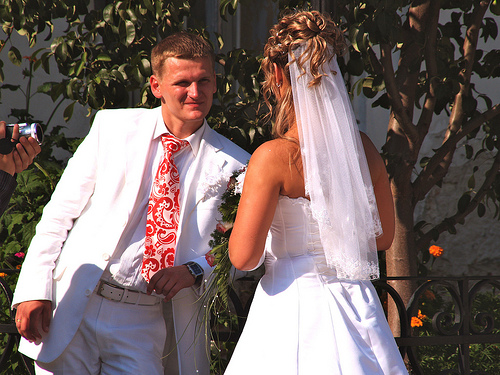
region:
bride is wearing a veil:
[277, 34, 401, 299]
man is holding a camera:
[6, 114, 61, 184]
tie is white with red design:
[130, 118, 185, 305]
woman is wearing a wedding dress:
[259, 153, 381, 350]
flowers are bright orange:
[405, 231, 479, 370]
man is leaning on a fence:
[173, 105, 308, 288]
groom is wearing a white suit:
[59, 111, 230, 361]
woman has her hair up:
[270, 15, 352, 77]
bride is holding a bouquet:
[185, 162, 275, 275]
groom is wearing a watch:
[170, 241, 224, 309]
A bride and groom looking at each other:
[70, 67, 370, 303]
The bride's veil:
[285, 57, 395, 274]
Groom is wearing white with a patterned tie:
[142, 77, 220, 353]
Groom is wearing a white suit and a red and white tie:
[37, 70, 228, 348]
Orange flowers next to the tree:
[411, 205, 446, 356]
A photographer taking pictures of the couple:
[0, 102, 38, 223]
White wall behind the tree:
[372, 0, 490, 215]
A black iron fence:
[302, 275, 492, 353]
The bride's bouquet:
[201, 170, 256, 311]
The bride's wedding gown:
[217, 169, 414, 372]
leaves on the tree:
[82, 31, 109, 60]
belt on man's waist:
[97, 285, 154, 304]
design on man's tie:
[156, 170, 174, 241]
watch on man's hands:
[180, 256, 205, 283]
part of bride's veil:
[300, 99, 352, 177]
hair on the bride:
[306, 41, 335, 92]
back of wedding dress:
[271, 283, 358, 351]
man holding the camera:
[0, 117, 42, 179]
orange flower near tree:
[420, 237, 450, 264]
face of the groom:
[158, 61, 222, 121]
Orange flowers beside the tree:
[385, 223, 461, 343]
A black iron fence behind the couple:
[215, 271, 491, 366]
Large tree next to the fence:
[361, 30, 441, 335]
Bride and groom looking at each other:
[45, 60, 411, 366]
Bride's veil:
[240, 55, 395, 290]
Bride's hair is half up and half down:
[260, 35, 345, 155]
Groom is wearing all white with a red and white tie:
[70, 65, 225, 371]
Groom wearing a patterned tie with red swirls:
[151, 115, 181, 295]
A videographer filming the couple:
[2, 101, 64, 199]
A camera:
[2, 111, 54, 188]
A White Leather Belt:
[97, 275, 169, 322]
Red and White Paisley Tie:
[135, 127, 185, 302]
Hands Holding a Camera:
[0, 110, 45, 190]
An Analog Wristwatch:
[185, 257, 216, 304]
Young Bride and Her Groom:
[110, 5, 415, 271]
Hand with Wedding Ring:
[6, 295, 66, 362]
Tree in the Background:
[365, 0, 495, 270]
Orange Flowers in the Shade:
[410, 235, 445, 326]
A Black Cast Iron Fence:
[390, 270, 496, 365]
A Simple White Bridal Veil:
[267, 7, 408, 283]